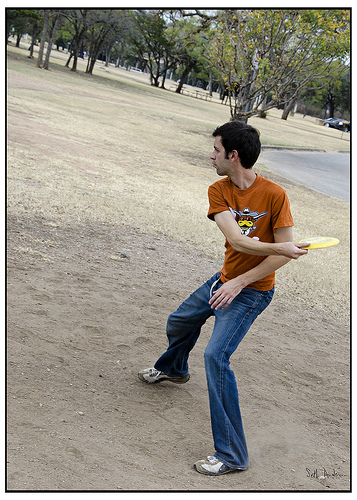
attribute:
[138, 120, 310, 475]
man — looking, young, standing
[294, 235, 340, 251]
frisbee — yellow, round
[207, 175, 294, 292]
shirt — orange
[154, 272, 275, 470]
jeans — blue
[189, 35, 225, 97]
tree — distant, green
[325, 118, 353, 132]
car — black, parked, small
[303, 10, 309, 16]
leaf — green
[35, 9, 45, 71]
trunk — white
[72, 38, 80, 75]
trunk — dark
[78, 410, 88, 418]
rock — white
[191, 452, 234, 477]
sneaker — white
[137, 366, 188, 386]
shoe — white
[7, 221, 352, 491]
sand — loose, gray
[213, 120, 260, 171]
hair — black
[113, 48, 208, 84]
building — distant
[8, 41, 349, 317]
grass — dormant